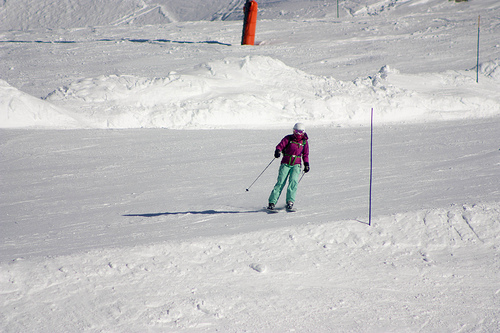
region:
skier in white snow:
[262, 123, 314, 208]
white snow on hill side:
[84, 190, 126, 227]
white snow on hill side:
[167, 296, 205, 323]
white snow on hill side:
[336, 249, 394, 302]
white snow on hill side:
[76, 181, 122, 218]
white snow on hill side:
[129, 153, 167, 179]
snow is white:
[396, 270, 468, 330]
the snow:
[303, 266, 346, 315]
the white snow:
[293, 235, 397, 307]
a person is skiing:
[271, 128, 317, 217]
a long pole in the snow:
[363, 103, 378, 220]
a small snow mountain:
[211, 64, 283, 131]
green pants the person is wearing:
[274, 162, 296, 203]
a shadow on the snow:
[121, 196, 236, 218]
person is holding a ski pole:
[271, 150, 285, 161]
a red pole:
[238, 1, 260, 45]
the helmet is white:
[288, 117, 308, 147]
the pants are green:
[265, 163, 312, 217]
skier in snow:
[281, 126, 313, 214]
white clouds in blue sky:
[88, 32, 139, 76]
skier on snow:
[268, 118, 328, 238]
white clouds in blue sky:
[137, 66, 189, 101]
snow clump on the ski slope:
[107, 257, 122, 274]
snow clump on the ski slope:
[250, 257, 263, 277]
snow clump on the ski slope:
[226, 266, 236, 272]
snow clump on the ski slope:
[215, 241, 226, 247]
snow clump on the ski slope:
[8, 252, 24, 263]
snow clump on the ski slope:
[420, 245, 428, 260]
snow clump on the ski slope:
[375, 222, 383, 233]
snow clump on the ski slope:
[380, 62, 390, 74]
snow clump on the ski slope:
[241, 52, 247, 68]